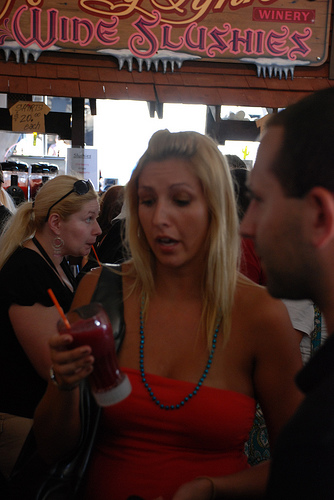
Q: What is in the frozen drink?
A: Straw.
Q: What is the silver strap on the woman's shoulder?
A: Purse.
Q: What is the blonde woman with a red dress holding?
A: A drink.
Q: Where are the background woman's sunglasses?
A: On her head.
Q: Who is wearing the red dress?
A: The blonde woman in front.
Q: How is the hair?
A: Long.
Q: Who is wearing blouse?
A: A lady.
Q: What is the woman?
A: Blonde.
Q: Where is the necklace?
A: On woman.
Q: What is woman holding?
A: Cup.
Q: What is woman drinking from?
A: Straw.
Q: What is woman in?
A: Pink dress.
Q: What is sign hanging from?
A: Ceiling.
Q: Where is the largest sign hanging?
A: From ceiling.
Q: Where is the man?
A: Standing beside woman.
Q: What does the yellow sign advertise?
A: Shirts.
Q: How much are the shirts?
A: $20.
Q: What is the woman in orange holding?
A: Cup.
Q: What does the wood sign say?
A: Wine slushies.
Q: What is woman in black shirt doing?
A: Drinking from straw.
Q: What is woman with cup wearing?
A: Orange tube top.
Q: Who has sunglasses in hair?
A: Woman in black.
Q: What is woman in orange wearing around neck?
A: Blue bead necklace.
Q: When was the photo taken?
A: Daytime.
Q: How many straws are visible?
A: Two.